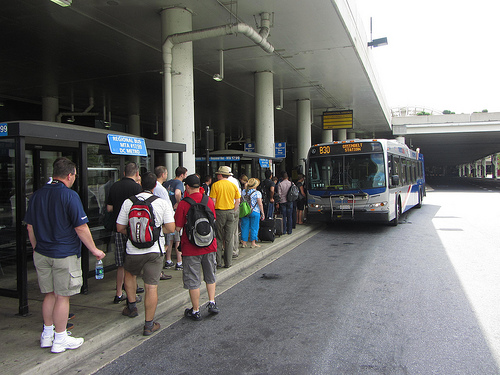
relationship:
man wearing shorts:
[104, 161, 140, 303] [115, 230, 128, 269]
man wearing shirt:
[208, 165, 240, 271] [207, 179, 242, 214]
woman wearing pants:
[242, 176, 267, 249] [241, 212, 261, 240]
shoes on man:
[37, 329, 85, 354] [25, 160, 101, 354]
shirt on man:
[207, 177, 244, 211] [209, 162, 243, 269]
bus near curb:
[301, 134, 426, 226] [1, 216, 319, 373]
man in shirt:
[176, 174, 223, 320] [121, 191, 215, 279]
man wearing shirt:
[208, 166, 240, 267] [209, 176, 240, 211]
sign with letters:
[107, 133, 149, 158] [113, 136, 144, 155]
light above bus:
[344, 4, 424, 83] [265, 63, 476, 318]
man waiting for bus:
[176, 174, 223, 320] [307, 136, 424, 228]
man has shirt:
[21, 155, 104, 355] [25, 177, 95, 257]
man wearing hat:
[171, 170, 223, 320] [182, 168, 210, 191]